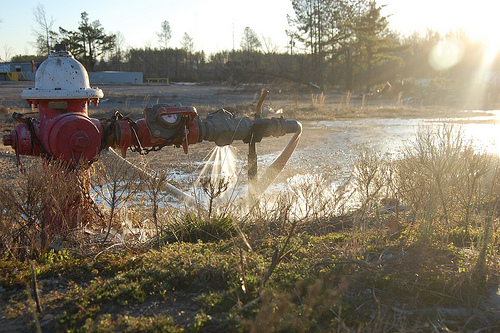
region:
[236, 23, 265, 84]
a tree in a distance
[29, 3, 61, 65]
a tree in a distance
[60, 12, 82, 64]
a tree in a distance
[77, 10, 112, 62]
a tree in a distance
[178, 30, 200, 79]
a tree in a distance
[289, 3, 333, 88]
a tree in a distance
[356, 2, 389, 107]
a tree in a distance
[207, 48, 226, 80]
a tree in a distance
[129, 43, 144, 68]
a tree in a distance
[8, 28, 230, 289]
Fire hydrant in a grassy field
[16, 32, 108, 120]
White cap on fire hydrant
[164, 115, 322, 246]
Water spraying from hydrant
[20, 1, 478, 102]
Trees in the background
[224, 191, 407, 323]
Branches in the grass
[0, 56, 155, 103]
Building in far background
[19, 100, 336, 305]
Water hose hanging from hydrant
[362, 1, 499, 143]
Glare of bright light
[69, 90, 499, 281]
Large puddle of water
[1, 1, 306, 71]
Bright blue skies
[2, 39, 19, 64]
a tree in a distance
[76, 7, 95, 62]
a tree in a distance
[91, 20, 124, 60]
a tree in a distance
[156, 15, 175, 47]
a tree in a distance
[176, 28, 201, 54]
a tree in a distance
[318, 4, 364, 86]
a tree in a distance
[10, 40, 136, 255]
A red hydrant with a white top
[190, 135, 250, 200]
Water spraying out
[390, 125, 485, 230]
Bare leafless bushes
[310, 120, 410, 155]
A reservoir of water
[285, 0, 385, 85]
A group of tall trees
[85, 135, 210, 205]
A hose connecting a water reservoir to a hydrant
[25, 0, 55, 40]
A bare leafless tree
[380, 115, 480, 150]
Light reflecting on water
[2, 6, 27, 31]
Blue sky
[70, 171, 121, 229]
A chain on a hydrant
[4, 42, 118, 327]
a red fire hydrant in a field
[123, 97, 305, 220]
a fire hose is connected to the hydrant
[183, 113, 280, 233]
the connection is spraying water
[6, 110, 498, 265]
a river is behind the hydrant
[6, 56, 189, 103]
a building is in a clearing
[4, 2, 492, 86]
trees are on the horizon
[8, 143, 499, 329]
weeds are on the river bank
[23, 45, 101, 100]
the fire hydrant has a white cap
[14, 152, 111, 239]
chains are on the hydrant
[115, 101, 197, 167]
a chain is on the connection to the hydrant